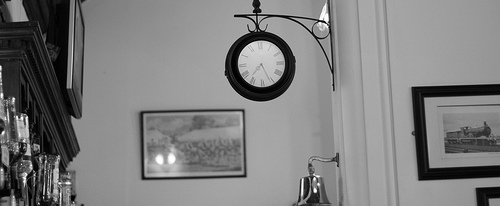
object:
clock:
[223, 31, 296, 102]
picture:
[137, 108, 246, 180]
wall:
[67, 0, 337, 206]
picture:
[410, 84, 499, 181]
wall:
[384, 0, 499, 206]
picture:
[475, 186, 499, 205]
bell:
[292, 175, 332, 205]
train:
[446, 121, 496, 146]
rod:
[232, 0, 335, 92]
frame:
[411, 84, 499, 181]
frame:
[475, 187, 500, 206]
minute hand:
[259, 63, 270, 82]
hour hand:
[251, 63, 262, 76]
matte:
[423, 94, 499, 168]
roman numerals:
[238, 42, 286, 88]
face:
[236, 40, 286, 88]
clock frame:
[224, 29, 296, 101]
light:
[155, 153, 176, 166]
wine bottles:
[0, 96, 33, 205]